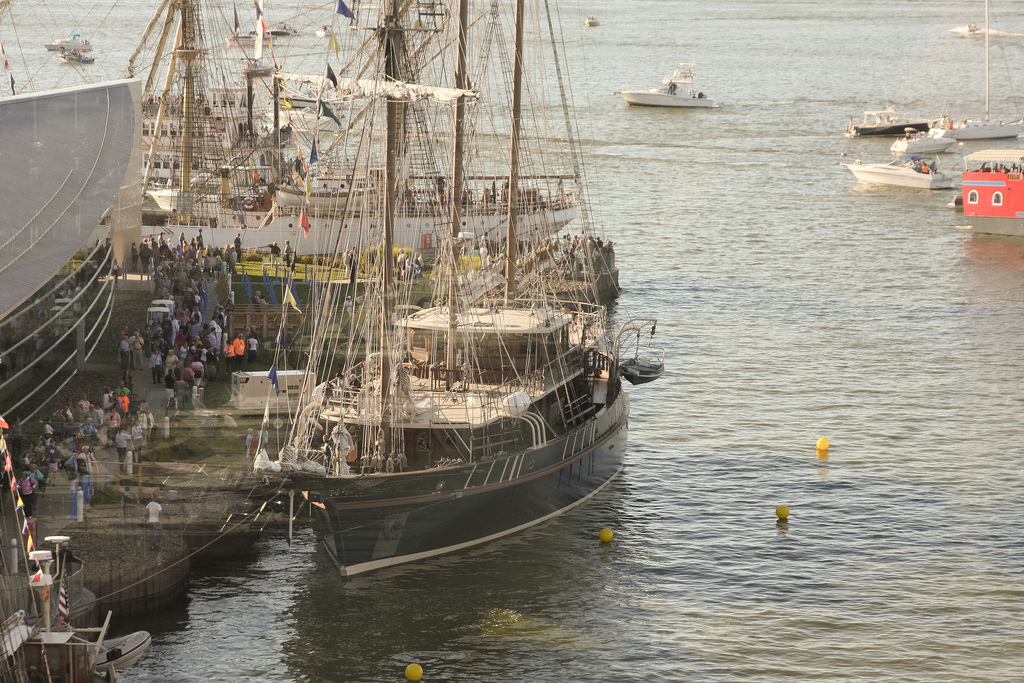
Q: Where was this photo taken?
A: At a pier.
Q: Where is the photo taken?
A: Ocean.